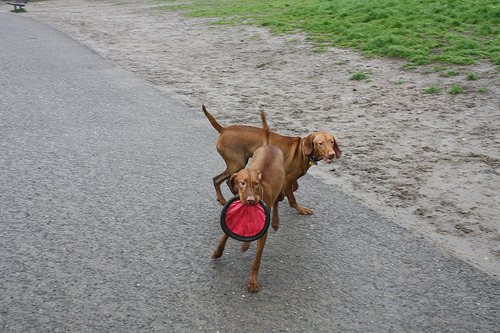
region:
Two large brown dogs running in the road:
[183, 90, 367, 295]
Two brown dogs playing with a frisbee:
[170, 95, 367, 314]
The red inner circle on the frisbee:
[227, 196, 267, 238]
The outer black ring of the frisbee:
[220, 193, 275, 245]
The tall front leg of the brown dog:
[245, 195, 286, 296]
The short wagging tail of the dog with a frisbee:
[254, 109, 276, 144]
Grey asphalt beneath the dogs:
[286, 236, 391, 326]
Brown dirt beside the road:
[372, 86, 477, 223]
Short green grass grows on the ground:
[345, 8, 489, 46]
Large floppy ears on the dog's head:
[302, 132, 348, 155]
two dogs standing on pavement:
[196, 98, 344, 296]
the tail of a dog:
[200, 103, 227, 140]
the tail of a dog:
[255, 105, 275, 145]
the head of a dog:
[299, 130, 347, 167]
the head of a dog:
[222, 170, 272, 212]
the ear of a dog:
[298, 133, 317, 160]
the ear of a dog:
[333, 133, 343, 163]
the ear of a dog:
[223, 170, 239, 192]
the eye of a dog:
[236, 177, 248, 188]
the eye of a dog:
[315, 138, 327, 150]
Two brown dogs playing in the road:
[170, 98, 382, 300]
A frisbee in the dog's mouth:
[212, 195, 275, 242]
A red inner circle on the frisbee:
[226, 200, 269, 235]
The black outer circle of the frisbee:
[217, 191, 275, 246]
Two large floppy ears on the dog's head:
[302, 130, 349, 160]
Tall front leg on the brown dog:
[247, 201, 279, 301]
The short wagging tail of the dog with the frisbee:
[256, 107, 278, 155]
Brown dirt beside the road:
[389, 113, 487, 230]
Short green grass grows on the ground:
[362, 12, 474, 58]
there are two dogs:
[185, 81, 379, 331]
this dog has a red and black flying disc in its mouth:
[192, 93, 307, 307]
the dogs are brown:
[172, 54, 345, 309]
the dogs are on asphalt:
[144, 43, 353, 324]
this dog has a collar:
[292, 110, 349, 183]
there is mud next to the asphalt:
[160, 32, 497, 244]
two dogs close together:
[191, 117, 379, 281]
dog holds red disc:
[205, 175, 290, 268]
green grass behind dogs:
[309, 2, 449, 92]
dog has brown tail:
[185, 107, 237, 147]